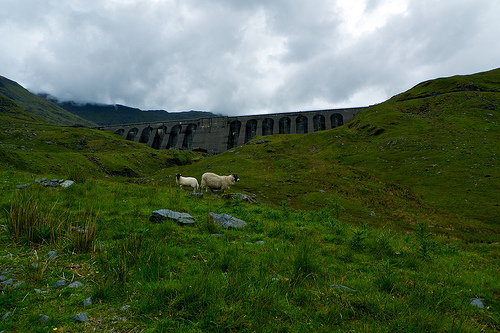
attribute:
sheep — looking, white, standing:
[203, 170, 237, 191]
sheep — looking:
[176, 172, 201, 191]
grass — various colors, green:
[348, 142, 477, 227]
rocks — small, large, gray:
[209, 208, 248, 234]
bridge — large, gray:
[101, 107, 364, 153]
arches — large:
[231, 122, 239, 149]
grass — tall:
[13, 189, 336, 329]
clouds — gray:
[228, 12, 295, 90]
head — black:
[233, 171, 238, 184]